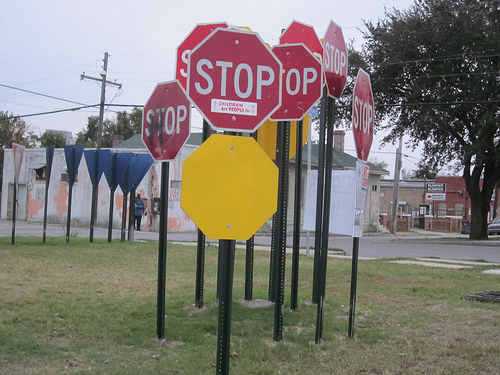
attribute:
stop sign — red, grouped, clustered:
[186, 26, 283, 136]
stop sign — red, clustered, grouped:
[141, 80, 193, 161]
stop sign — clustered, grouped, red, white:
[268, 43, 324, 123]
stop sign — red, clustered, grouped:
[321, 19, 350, 100]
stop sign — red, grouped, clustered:
[351, 67, 378, 161]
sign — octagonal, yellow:
[178, 131, 280, 242]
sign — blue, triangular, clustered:
[62, 143, 85, 179]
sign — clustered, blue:
[82, 148, 110, 185]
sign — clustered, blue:
[108, 151, 132, 192]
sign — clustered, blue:
[125, 152, 156, 194]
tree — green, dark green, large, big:
[308, 0, 496, 240]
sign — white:
[12, 143, 29, 184]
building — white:
[1, 148, 195, 232]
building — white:
[120, 129, 392, 237]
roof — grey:
[114, 129, 387, 173]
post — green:
[154, 160, 172, 339]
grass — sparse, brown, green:
[1, 237, 499, 375]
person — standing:
[131, 190, 147, 231]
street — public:
[1, 217, 500, 267]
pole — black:
[315, 96, 337, 342]